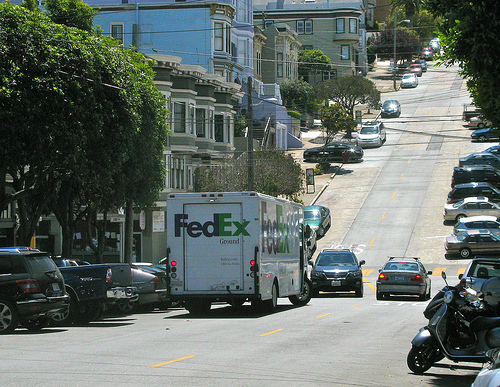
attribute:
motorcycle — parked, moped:
[408, 275, 495, 373]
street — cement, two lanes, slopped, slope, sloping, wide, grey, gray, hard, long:
[33, 70, 485, 387]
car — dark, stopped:
[376, 256, 433, 301]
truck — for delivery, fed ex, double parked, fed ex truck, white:
[167, 191, 312, 314]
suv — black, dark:
[306, 247, 367, 296]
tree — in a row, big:
[1, 3, 58, 246]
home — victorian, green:
[143, 56, 239, 199]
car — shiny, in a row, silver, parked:
[443, 197, 500, 224]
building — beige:
[255, 8, 361, 78]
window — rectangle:
[172, 101, 185, 131]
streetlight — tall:
[392, 15, 413, 74]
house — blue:
[101, 3, 234, 80]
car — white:
[359, 120, 386, 148]